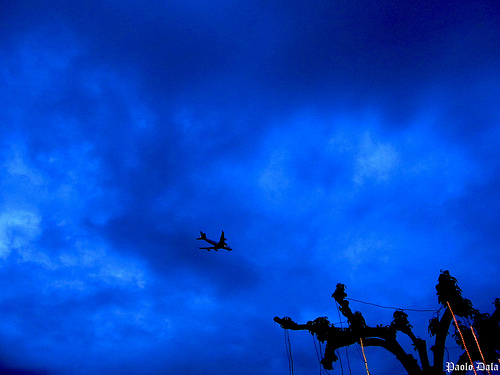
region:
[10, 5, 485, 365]
blended sky of light and dark blue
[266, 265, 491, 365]
gnarls on curved and extended branches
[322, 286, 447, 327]
lines between branches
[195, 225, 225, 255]
large curve of wings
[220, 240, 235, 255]
pointy edge of nose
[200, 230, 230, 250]
oval shape of body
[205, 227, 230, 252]
bumps in front of wings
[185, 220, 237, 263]
plane against dark cloud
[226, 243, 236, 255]
front of a plane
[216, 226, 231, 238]
wing of a plane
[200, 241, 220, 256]
wing of a plane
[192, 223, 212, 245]
back of a plane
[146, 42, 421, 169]
blue sky with clouds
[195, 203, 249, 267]
plane in the sky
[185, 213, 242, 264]
plane flying in the sky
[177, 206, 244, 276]
plane in the air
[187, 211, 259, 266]
the plane is flying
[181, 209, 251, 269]
the plane is flying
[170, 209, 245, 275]
the plane is flying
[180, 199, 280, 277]
the plane is flying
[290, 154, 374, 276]
the sky is cloudy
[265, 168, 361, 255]
the sky is cloudy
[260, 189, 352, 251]
the sky is cloudy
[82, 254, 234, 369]
the sky is cloudy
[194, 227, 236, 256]
Plane flying under the clouds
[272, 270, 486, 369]
Silhouette of a tree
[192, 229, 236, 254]
A plane flying low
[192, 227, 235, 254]
Underside of a low-flying plane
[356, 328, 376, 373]
Decorative lighting hanging from a tree branch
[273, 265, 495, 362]
Tree with decorative lights hanging from it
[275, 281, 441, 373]
A tree underneath a dark, cloudy sky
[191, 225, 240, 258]
Plane flying beneath dark clouds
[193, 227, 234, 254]
A plane in the sky.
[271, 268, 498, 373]
Branches on a tree.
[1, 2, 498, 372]
A cloudy blue sky.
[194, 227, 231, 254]
A jet in the sky.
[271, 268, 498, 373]
Branches with a net.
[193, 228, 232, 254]
A plane in the air.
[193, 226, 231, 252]
A jet in the air.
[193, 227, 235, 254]
A plane flying in the sky.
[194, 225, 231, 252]
A passenger plane in the sky.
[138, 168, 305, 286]
plane in the air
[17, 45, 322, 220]
clouds in the sky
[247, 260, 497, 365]
a large tree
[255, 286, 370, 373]
items hanging on a tree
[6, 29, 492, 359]
a dark blue sky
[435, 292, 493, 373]
lights hanging from a tree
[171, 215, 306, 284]
plane flying towards the right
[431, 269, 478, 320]
leaves on a tree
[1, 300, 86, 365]
a royal blue colored sky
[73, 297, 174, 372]
a royal blue colored sky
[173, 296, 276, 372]
a royal blue colored sky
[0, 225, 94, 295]
a royal blue colored sky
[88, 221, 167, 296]
a royal blue colored sky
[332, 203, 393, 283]
a royal blue colored sky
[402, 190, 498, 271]
a royal blue colored sky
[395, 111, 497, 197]
a royal blue colored sky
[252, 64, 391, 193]
a royal blue colored sky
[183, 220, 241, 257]
plane in the sky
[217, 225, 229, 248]
right wing on the plane